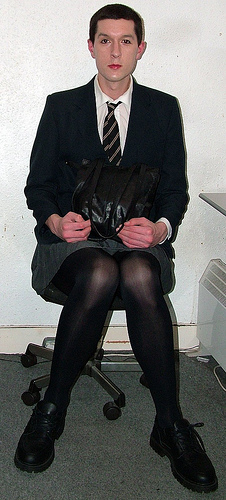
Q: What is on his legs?
A: Tights.